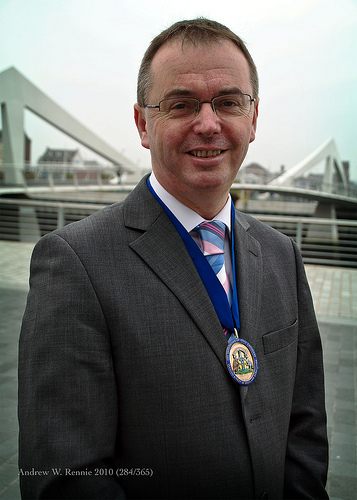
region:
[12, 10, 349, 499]
this man is wearing a blue medal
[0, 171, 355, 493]
he is dressed in a nice suit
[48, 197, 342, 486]
the suit is grey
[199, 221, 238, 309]
his tie is colorful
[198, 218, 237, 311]
his tie is pink, blue &white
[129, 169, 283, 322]
his shirt is white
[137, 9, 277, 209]
the man is wearing glasses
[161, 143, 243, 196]
the man is smiling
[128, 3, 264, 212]
the man has very short hair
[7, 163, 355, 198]
a bridge is in the background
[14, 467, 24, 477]
The white letter a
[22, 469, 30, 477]
the white letter n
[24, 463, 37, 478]
the white letter d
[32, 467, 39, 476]
the white letter r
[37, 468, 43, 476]
the white letter e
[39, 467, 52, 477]
the white letter w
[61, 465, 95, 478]
the white word rennie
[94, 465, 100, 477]
the white number 2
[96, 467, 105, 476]
the white number 0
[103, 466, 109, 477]
the white number one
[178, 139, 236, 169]
the man is smiling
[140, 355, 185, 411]
the jacket is gray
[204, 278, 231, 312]
the ribbon is blue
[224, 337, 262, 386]
the medalon is gold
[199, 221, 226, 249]
the tie is striped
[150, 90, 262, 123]
the man is wearing glasses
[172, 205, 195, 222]
the shirt is white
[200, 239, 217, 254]
the tie has a pink stripe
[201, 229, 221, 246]
the stripe on the tie is blue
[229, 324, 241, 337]
the ring is gold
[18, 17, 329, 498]
Middle-aged man wearing a medal.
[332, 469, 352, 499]
Part of concrete pavement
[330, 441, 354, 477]
Part of concrete pavement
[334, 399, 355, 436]
Part of concrete pavement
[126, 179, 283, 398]
Blue ribbon around a neck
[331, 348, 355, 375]
Part of concrete pavement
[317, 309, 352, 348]
Part of concrete pavement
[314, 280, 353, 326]
Part of concrete pavement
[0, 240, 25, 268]
Part of concrete pavement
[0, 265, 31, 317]
Part of concrete pavement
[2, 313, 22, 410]
Part of concrete pavement